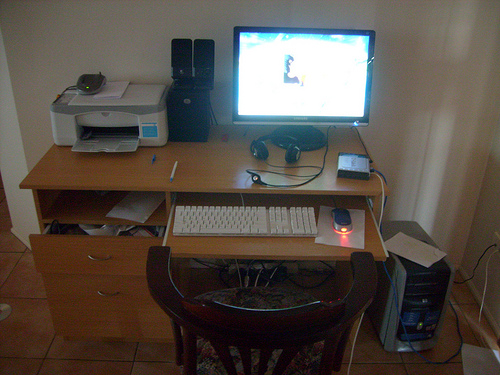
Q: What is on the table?
A: Computer.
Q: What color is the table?
A: Brown.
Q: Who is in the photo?
A: No one.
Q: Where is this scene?
A: Office.